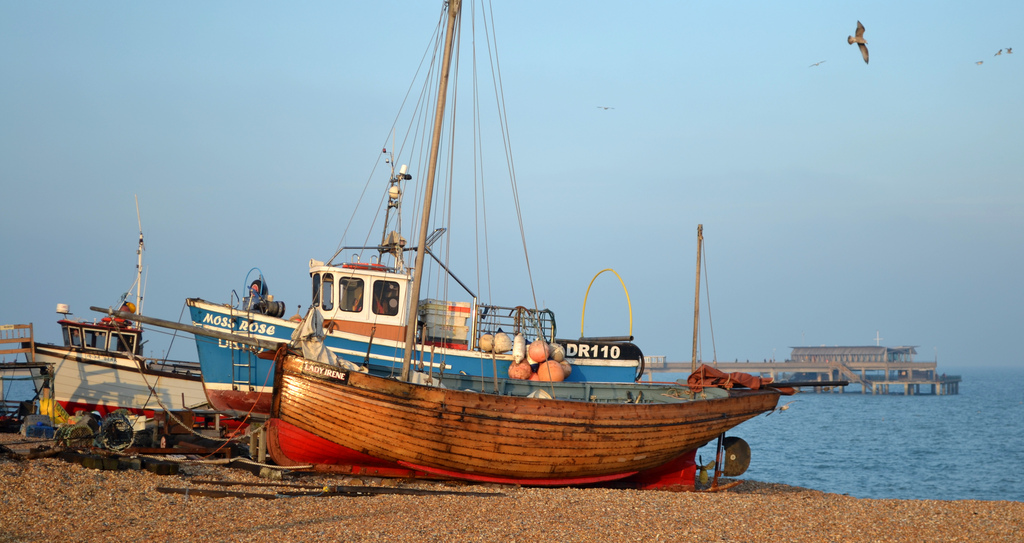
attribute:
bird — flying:
[845, 26, 866, 53]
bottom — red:
[266, 414, 699, 500]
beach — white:
[0, 415, 1024, 536]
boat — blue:
[84, 4, 847, 501]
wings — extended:
[861, 20, 872, 72]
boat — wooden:
[156, 238, 839, 507]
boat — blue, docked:
[169, 248, 794, 506]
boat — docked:
[177, 272, 303, 411]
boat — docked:
[28, 300, 208, 447]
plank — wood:
[142, 463, 367, 511]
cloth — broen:
[665, 351, 836, 431]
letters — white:
[555, 331, 629, 360]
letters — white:
[570, 319, 638, 369]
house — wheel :
[11, 11, 778, 498]